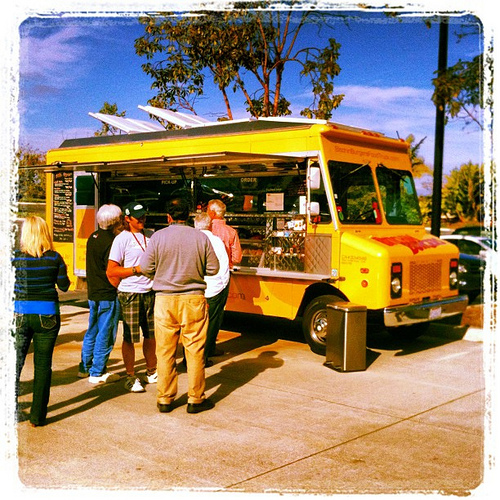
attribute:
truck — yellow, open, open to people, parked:
[52, 136, 476, 323]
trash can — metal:
[318, 293, 376, 379]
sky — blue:
[65, 38, 118, 89]